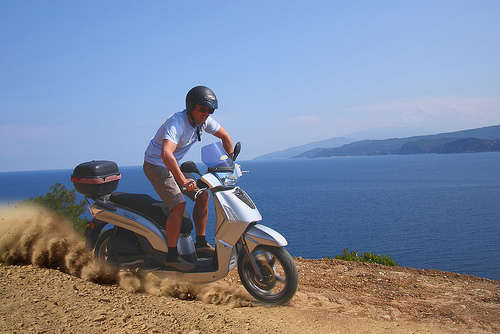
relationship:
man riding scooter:
[137, 81, 234, 259] [62, 134, 313, 313]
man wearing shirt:
[137, 81, 234, 259] [142, 109, 222, 172]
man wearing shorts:
[137, 81, 234, 259] [138, 162, 194, 208]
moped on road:
[69, 141, 298, 306] [1, 250, 498, 332]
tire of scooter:
[236, 242, 293, 303] [70, 141, 299, 304]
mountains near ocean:
[311, 113, 500, 158] [0, 148, 497, 280]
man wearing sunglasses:
[137, 81, 234, 259] [200, 106, 215, 114]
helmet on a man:
[185, 83, 219, 110] [137, 81, 234, 259]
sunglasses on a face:
[200, 106, 215, 114] [187, 92, 220, 127]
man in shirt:
[137, 81, 234, 259] [168, 119, 190, 158]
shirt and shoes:
[168, 119, 190, 158] [162, 242, 227, 272]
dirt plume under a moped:
[0, 199, 255, 309] [69, 141, 298, 306]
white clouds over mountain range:
[351, 98, 469, 130] [313, 122, 496, 150]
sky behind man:
[4, 3, 499, 169] [137, 81, 234, 259]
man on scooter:
[137, 81, 234, 259] [70, 141, 299, 304]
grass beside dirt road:
[333, 247, 398, 264] [3, 231, 498, 332]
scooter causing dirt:
[70, 141, 299, 304] [0, 195, 92, 278]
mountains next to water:
[311, 113, 489, 171] [244, 163, 431, 210]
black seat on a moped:
[107, 190, 193, 237] [69, 141, 298, 306]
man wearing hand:
[137, 81, 234, 259] [184, 177, 199, 193]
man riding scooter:
[137, 81, 234, 259] [70, 141, 299, 304]